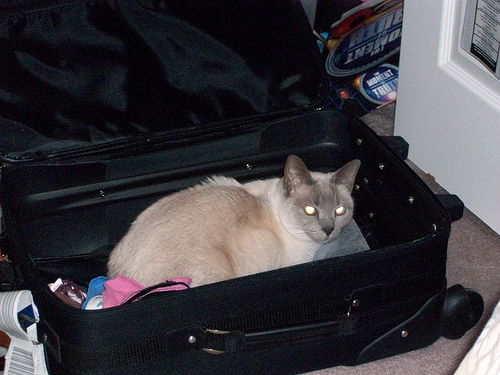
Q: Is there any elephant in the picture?
A: No, there are no elephants.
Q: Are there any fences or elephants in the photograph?
A: No, there are no elephants or fences.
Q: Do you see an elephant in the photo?
A: No, there are no elephants.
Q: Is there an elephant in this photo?
A: No, there are no elephants.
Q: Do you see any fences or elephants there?
A: No, there are no elephants or fences.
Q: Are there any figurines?
A: No, there are no figurines.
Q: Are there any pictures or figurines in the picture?
A: No, there are no figurines or pictures.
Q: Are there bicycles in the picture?
A: No, there are no bicycles.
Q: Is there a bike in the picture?
A: No, there are no bikes.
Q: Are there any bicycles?
A: No, there are no bicycles.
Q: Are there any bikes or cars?
A: No, there are no bikes or cars.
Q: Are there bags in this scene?
A: Yes, there is a bag.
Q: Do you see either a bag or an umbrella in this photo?
A: Yes, there is a bag.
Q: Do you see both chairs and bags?
A: No, there is a bag but no chairs.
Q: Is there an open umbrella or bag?
A: Yes, there is an open bag.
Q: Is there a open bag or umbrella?
A: Yes, there is an open bag.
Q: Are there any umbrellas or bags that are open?
A: Yes, the bag is open.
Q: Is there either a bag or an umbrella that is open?
A: Yes, the bag is open.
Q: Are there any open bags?
A: Yes, there is an open bag.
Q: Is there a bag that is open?
A: Yes, there is a bag that is open.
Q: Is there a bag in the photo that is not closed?
A: Yes, there is a open bag.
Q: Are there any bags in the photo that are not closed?
A: Yes, there is a open bag.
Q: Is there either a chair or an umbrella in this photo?
A: No, there are no chairs or umbrellas.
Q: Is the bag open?
A: Yes, the bag is open.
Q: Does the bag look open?
A: Yes, the bag is open.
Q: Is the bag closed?
A: No, the bag is open.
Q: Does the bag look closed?
A: No, the bag is open.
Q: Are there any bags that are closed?
A: No, there is a bag but it is open.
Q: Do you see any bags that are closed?
A: No, there is a bag but it is open.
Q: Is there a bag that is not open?
A: No, there is a bag but it is open.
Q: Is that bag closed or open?
A: The bag is open.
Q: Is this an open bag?
A: Yes, this is an open bag.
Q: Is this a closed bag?
A: No, this is an open bag.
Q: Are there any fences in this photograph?
A: No, there are no fences.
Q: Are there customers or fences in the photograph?
A: No, there are no fences or customers.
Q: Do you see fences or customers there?
A: No, there are no fences or customers.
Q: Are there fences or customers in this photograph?
A: No, there are no fences or customers.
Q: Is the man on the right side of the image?
A: Yes, the man is on the right of the image.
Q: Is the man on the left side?
A: No, the man is on the right of the image.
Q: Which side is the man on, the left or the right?
A: The man is on the right of the image.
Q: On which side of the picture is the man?
A: The man is on the right of the image.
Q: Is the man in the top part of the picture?
A: Yes, the man is in the top of the image.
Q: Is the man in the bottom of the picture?
A: No, the man is in the top of the image.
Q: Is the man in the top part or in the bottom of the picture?
A: The man is in the top of the image.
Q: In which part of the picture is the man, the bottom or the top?
A: The man is in the top of the image.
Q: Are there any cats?
A: Yes, there is a cat.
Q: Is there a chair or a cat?
A: Yes, there is a cat.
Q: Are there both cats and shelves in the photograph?
A: No, there is a cat but no shelves.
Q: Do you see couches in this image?
A: No, there are no couches.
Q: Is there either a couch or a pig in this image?
A: No, there are no couches or pigs.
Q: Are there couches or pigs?
A: No, there are no couches or pigs.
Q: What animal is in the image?
A: The animal is a cat.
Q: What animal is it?
A: The animal is a cat.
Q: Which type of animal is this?
A: This is a cat.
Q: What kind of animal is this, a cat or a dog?
A: This is a cat.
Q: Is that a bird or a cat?
A: That is a cat.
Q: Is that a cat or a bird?
A: That is a cat.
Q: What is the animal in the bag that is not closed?
A: The animal is a cat.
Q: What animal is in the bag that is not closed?
A: The animal is a cat.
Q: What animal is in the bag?
A: The animal is a cat.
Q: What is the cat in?
A: The cat is in the bag.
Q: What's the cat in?
A: The cat is in the bag.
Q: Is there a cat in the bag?
A: Yes, there is a cat in the bag.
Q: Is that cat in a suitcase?
A: No, the cat is in a bag.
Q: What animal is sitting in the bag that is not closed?
A: The cat is sitting in the bag.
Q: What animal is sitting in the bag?
A: The cat is sitting in the bag.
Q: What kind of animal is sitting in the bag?
A: The animal is a cat.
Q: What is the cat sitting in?
A: The cat is sitting in the bag.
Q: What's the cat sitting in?
A: The cat is sitting in the bag.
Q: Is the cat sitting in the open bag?
A: Yes, the cat is sitting in the bag.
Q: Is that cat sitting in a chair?
A: No, the cat is sitting in the bag.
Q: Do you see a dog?
A: No, there are no dogs.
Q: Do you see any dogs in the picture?
A: No, there are no dogs.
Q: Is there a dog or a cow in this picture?
A: No, there are no dogs or cows.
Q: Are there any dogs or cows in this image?
A: No, there are no dogs or cows.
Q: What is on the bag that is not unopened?
A: The tag is on the bag.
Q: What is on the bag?
A: The tag is on the bag.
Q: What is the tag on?
A: The tag is on the bag.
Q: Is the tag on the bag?
A: Yes, the tag is on the bag.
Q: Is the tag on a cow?
A: No, the tag is on the bag.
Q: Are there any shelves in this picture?
A: No, there are no shelves.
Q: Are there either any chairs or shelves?
A: No, there are no shelves or chairs.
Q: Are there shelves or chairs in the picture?
A: No, there are no shelves or chairs.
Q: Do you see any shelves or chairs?
A: No, there are no shelves or chairs.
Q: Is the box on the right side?
A: Yes, the box is on the right of the image.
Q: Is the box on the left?
A: No, the box is on the right of the image.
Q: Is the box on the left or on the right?
A: The box is on the right of the image.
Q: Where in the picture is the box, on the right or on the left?
A: The box is on the right of the image.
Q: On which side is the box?
A: The box is on the right of the image.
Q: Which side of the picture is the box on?
A: The box is on the right of the image.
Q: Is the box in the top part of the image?
A: Yes, the box is in the top of the image.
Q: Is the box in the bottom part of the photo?
A: No, the box is in the top of the image.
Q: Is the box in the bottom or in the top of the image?
A: The box is in the top of the image.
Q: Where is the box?
A: The box is on the floor.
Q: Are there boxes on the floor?
A: Yes, there is a box on the floor.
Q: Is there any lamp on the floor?
A: No, there is a box on the floor.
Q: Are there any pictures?
A: No, there are no pictures.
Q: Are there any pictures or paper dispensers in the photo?
A: No, there are no pictures or paper dispensers.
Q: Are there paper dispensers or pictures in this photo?
A: No, there are no pictures or paper dispensers.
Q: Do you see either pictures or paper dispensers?
A: No, there are no pictures or paper dispensers.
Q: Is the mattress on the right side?
A: Yes, the mattress is on the right of the image.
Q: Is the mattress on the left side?
A: No, the mattress is on the right of the image.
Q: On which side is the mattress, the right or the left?
A: The mattress is on the right of the image.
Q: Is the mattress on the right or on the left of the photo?
A: The mattress is on the right of the image.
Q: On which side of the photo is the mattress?
A: The mattress is on the right of the image.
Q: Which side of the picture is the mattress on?
A: The mattress is on the right of the image.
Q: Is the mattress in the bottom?
A: Yes, the mattress is in the bottom of the image.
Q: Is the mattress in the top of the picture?
A: No, the mattress is in the bottom of the image.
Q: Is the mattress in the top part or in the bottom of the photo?
A: The mattress is in the bottom of the image.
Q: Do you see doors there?
A: Yes, there is a door.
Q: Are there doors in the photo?
A: Yes, there is a door.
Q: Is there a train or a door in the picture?
A: Yes, there is a door.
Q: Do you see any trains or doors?
A: Yes, there is a door.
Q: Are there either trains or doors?
A: Yes, there is a door.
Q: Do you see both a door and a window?
A: Yes, there are both a door and a window.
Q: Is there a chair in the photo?
A: No, there are no chairs.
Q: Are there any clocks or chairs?
A: No, there are no chairs or clocks.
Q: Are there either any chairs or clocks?
A: No, there are no chairs or clocks.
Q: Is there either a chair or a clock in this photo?
A: No, there are no chairs or clocks.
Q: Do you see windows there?
A: Yes, there is a window.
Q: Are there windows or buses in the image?
A: Yes, there is a window.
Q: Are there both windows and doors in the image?
A: Yes, there are both a window and a door.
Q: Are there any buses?
A: No, there are no buses.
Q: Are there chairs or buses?
A: No, there are no buses or chairs.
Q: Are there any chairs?
A: No, there are no chairs.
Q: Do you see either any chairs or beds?
A: No, there are no chairs or beds.